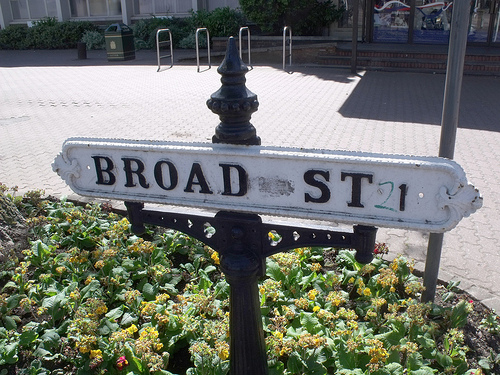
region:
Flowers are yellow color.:
[48, 252, 259, 362]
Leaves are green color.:
[41, 249, 212, 340]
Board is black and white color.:
[64, 135, 461, 226]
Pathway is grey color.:
[6, 56, 167, 139]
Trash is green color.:
[89, 18, 141, 70]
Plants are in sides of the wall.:
[6, 13, 233, 52]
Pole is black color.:
[195, 34, 282, 359]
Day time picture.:
[6, 28, 488, 330]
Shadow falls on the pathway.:
[21, 40, 465, 146]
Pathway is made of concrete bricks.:
[11, 78, 172, 135]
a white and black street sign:
[44, 131, 487, 232]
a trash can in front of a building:
[101, 21, 136, 58]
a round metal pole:
[419, 2, 472, 302]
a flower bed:
[1, 193, 486, 370]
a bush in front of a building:
[22, 20, 77, 40]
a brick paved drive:
[0, 65, 495, 280]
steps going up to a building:
[347, 35, 497, 71]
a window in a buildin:
[66, 0, 121, 19]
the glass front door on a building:
[470, 3, 499, 45]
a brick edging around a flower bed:
[373, 245, 499, 322]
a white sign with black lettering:
[52, 136, 480, 233]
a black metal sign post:
[202, 33, 270, 373]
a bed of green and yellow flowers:
[1, 185, 488, 372]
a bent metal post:
[153, 26, 175, 73]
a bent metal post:
[194, 27, 212, 71]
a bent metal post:
[280, 23, 292, 71]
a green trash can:
[103, 19, 136, 63]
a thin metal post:
[350, 5, 358, 70]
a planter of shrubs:
[0, 11, 247, 48]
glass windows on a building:
[368, 0, 498, 44]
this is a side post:
[58, 138, 465, 210]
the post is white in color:
[248, 155, 298, 202]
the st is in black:
[296, 172, 371, 210]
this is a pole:
[218, 214, 275, 373]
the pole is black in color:
[221, 235, 285, 370]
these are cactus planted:
[63, 246, 191, 355]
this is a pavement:
[315, 69, 427, 142]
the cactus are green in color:
[296, 275, 395, 365]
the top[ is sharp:
[223, 34, 243, 66]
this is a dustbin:
[103, 18, 138, 60]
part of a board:
[410, 152, 446, 207]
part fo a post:
[229, 288, 255, 341]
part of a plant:
[328, 303, 359, 343]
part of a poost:
[415, 253, 438, 298]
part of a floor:
[448, 244, 478, 284]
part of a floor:
[461, 250, 486, 286]